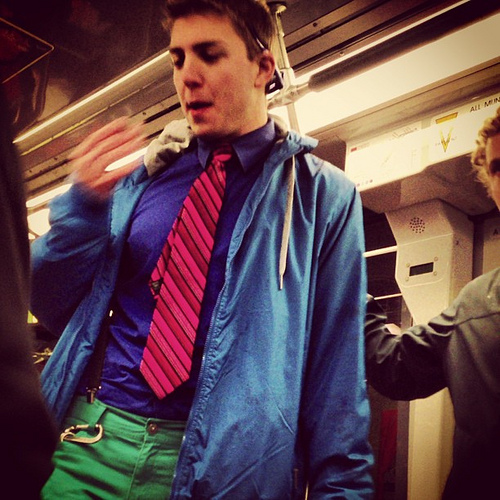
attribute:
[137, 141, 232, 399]
tie — striped, red, striped red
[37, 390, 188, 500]
pants — green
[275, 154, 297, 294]
lace — white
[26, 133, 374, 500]
jacket — blue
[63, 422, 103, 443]
carabiner — metal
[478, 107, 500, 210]
hair — blonde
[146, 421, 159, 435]
button — metal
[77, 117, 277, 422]
shirt — purple, blue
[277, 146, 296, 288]
string — white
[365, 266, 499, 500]
jacket — black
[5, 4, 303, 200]
bars — metal